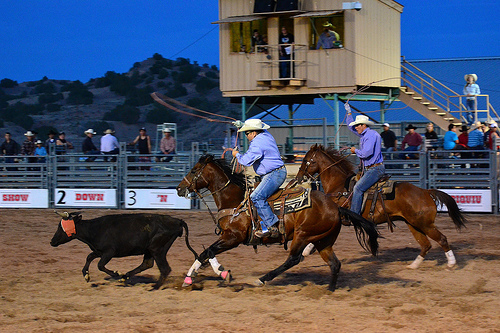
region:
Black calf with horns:
[49, 207, 203, 289]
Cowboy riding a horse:
[232, 116, 287, 237]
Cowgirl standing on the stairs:
[461, 71, 481, 126]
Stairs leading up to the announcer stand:
[400, 57, 498, 136]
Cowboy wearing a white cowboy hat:
[347, 114, 387, 224]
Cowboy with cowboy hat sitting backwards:
[100, 128, 122, 163]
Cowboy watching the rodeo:
[18, 129, 36, 169]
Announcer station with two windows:
[209, 0, 402, 97]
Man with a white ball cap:
[374, 122, 397, 158]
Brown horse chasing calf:
[176, 151, 382, 293]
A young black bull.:
[50, 207, 198, 288]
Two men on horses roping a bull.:
[47, 75, 466, 295]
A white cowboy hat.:
[236, 119, 271, 134]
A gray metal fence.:
[0, 141, 498, 188]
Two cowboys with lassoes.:
[149, 75, 464, 287]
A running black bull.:
[47, 206, 196, 291]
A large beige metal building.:
[212, 0, 404, 96]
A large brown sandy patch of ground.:
[2, 206, 498, 331]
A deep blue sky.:
[0, 0, 497, 80]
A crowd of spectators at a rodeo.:
[1, 18, 498, 169]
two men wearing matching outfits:
[234, 114, 388, 231]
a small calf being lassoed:
[42, 206, 190, 286]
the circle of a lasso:
[148, 89, 238, 127]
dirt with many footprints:
[356, 275, 497, 325]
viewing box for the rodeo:
[214, 5, 399, 97]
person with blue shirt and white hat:
[461, 70, 484, 123]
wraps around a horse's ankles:
[179, 255, 237, 289]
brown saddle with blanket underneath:
[278, 185, 315, 211]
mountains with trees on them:
[23, 48, 209, 123]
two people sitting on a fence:
[77, 127, 121, 164]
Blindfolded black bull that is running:
[48, 211, 198, 289]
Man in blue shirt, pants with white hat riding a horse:
[226, 116, 294, 240]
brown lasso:
[146, 85, 248, 173]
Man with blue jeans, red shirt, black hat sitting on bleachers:
[398, 122, 423, 162]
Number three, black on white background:
[123, 188, 138, 208]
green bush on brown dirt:
[102, 98, 142, 130]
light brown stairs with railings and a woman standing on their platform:
[401, 55, 498, 140]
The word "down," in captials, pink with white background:
[74, 192, 104, 201]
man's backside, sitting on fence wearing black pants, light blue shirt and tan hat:
[100, 128, 119, 160]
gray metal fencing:
[52, 153, 122, 187]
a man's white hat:
[348, 113, 378, 128]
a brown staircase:
[398, 65, 495, 132]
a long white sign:
[125, 189, 191, 211]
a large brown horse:
[180, 153, 383, 303]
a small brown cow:
[46, 208, 208, 293]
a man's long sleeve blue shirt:
[235, 132, 285, 176]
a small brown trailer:
[208, 0, 410, 97]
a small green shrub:
[98, 98, 140, 127]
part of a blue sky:
[404, 3, 499, 60]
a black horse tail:
[430, 188, 472, 230]